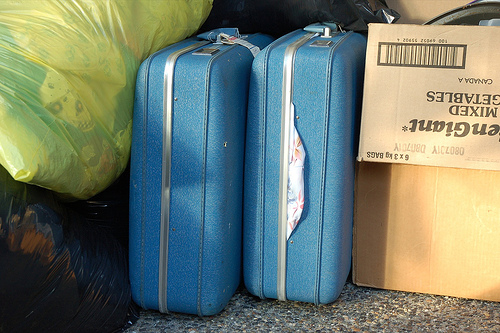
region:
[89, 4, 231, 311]
the suitcase is blue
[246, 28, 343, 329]
the suitcase is blue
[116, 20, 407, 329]
two vintage blue suitcases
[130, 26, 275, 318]
luggage is next to luggage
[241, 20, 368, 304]
luggage is next to luggage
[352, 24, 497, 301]
luggage is next to cardboard box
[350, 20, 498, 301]
cardboard box is brown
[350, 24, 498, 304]
cardboard box is next to luggage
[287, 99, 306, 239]
fabric sticking out of luggage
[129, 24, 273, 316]
luggage is next to yellow plastic bag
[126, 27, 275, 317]
luggage is next to black plastic bag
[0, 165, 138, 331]
black plastic bag beneath yellow plastic bag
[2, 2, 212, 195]
yellow plastic bag on top of black plastic bag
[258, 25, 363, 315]
suitcase on the ground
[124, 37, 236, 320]
suitcase on the ground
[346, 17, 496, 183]
cardboard box stacked outside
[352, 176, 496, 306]
cardboard box stacked outside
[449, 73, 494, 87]
writing on the box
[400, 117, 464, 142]
writing on the box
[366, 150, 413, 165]
writing on the box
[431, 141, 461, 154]
writing on the box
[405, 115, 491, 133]
writing on the box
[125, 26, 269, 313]
light blue luggage is next to luggage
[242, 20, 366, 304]
light blue luggage is next to luggage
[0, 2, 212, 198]
yellow plastic bag is full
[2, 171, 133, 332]
black plastic bag is full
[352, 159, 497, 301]
carboard box is brown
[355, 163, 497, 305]
cardboard box is next to luggage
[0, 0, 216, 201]
yellow bag is next to luggage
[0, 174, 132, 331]
black plastic bag is next to luggage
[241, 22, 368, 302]
luggage is next to cardboard box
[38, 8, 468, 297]
luggage, boxes and trash bags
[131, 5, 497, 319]
blue suitcases next to a box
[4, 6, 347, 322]
a plastic yellow bag and two suitcases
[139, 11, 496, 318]
the luggage is beside the boxes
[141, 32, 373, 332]
two blue suitcases are in this picture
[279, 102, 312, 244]
a white item is hanging out of the suitcase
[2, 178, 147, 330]
a black plastic bag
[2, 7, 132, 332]
two plastic bags in this photo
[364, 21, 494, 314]
two boxes piled on each other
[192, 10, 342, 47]
two blue suitcase handles